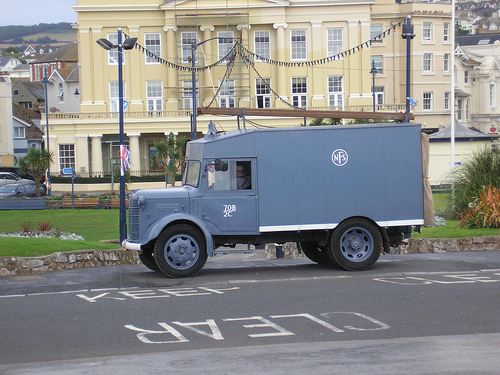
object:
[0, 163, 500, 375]
outdoors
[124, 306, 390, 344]
clear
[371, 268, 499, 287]
writing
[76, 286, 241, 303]
keep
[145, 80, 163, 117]
window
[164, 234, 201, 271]
rim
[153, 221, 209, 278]
tire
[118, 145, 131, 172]
flag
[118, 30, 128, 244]
pole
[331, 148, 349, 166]
logo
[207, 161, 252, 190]
driver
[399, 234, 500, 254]
step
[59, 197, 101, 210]
bench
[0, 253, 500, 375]
pavement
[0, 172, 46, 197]
car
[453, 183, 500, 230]
bush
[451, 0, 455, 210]
pole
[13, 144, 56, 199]
tree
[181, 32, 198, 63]
window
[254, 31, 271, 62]
window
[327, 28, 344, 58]
window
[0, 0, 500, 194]
building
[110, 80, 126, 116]
window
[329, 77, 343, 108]
window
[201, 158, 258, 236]
door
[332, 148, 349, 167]
letters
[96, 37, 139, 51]
lights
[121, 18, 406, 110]
christmas lights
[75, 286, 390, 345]
words